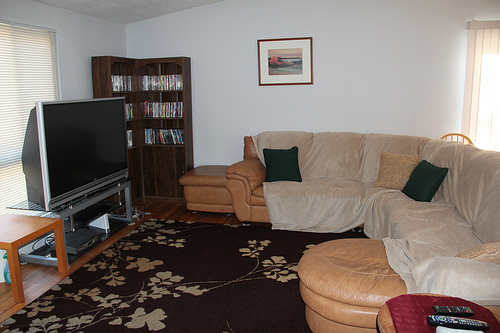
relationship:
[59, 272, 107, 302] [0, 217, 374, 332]
floral pattern on carpet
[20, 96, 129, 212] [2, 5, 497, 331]
television in living room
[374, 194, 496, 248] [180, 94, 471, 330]
sheet on sofa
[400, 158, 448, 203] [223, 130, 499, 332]
pillow on couch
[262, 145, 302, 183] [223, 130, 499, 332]
pillow on couch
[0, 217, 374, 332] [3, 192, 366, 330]
carpet on floor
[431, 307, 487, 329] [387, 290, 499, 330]
remotes on cloth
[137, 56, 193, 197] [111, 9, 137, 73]
bookcase in corner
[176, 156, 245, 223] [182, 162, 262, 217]
footrest beside sofa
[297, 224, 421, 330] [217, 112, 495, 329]
footrest in front of sofa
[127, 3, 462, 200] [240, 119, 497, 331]
wall behind couch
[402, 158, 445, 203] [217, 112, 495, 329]
pillow on sofa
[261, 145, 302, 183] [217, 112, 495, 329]
pillow on sofa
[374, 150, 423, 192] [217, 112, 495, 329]
pillow on sofa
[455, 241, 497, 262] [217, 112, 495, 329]
pillow on sofa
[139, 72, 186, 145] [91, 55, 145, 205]
books on bookcase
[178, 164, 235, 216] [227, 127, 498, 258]
footrest next to sofa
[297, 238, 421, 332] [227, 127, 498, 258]
footrest next to sofa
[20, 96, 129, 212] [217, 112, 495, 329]
television in front of sofa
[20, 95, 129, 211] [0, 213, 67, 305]
television on brown table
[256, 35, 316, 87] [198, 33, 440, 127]
picture on wall